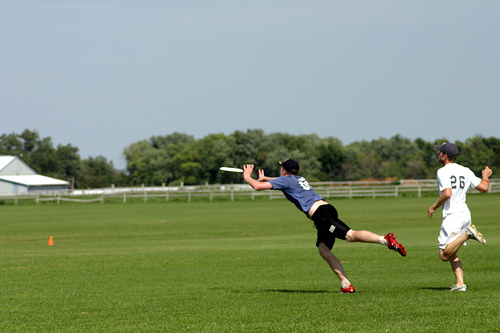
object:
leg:
[338, 229, 387, 244]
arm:
[470, 170, 490, 194]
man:
[424, 141, 494, 294]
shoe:
[384, 232, 408, 257]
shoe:
[339, 284, 356, 294]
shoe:
[465, 223, 488, 245]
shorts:
[310, 203, 351, 251]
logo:
[328, 224, 336, 233]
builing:
[0, 153, 71, 196]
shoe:
[448, 284, 466, 292]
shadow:
[263, 288, 336, 294]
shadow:
[416, 286, 451, 291]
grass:
[0, 184, 499, 333]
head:
[434, 141, 460, 162]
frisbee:
[219, 166, 243, 173]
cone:
[47, 235, 55, 246]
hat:
[433, 141, 460, 159]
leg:
[439, 230, 470, 262]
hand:
[242, 163, 255, 177]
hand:
[257, 168, 266, 181]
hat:
[278, 158, 301, 175]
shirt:
[435, 162, 482, 218]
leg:
[450, 254, 465, 285]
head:
[279, 158, 301, 177]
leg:
[317, 236, 349, 283]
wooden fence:
[0, 179, 500, 208]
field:
[0, 185, 500, 333]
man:
[241, 157, 407, 294]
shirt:
[265, 174, 328, 218]